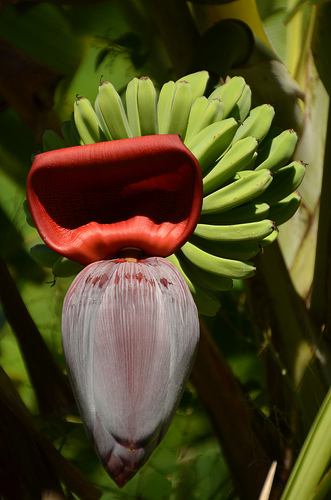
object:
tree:
[0, 0, 330, 498]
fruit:
[25, 70, 305, 489]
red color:
[27, 134, 203, 488]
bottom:
[61, 257, 201, 489]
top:
[25, 134, 204, 265]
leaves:
[171, 431, 213, 479]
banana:
[73, 70, 305, 319]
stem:
[279, 383, 330, 500]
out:
[73, 212, 196, 262]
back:
[31, 293, 60, 361]